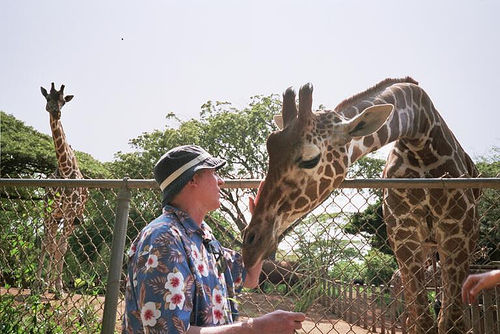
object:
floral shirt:
[123, 202, 249, 334]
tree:
[0, 111, 115, 179]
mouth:
[248, 255, 264, 269]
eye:
[297, 151, 324, 169]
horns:
[50, 82, 55, 92]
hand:
[247, 308, 306, 334]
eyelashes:
[300, 151, 323, 168]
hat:
[152, 143, 227, 209]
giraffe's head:
[239, 82, 394, 269]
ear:
[345, 103, 392, 137]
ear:
[270, 114, 284, 132]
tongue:
[242, 257, 263, 289]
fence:
[0, 170, 499, 333]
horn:
[60, 84, 65, 93]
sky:
[0, 0, 498, 169]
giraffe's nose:
[240, 229, 258, 245]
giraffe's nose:
[54, 109, 62, 116]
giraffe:
[32, 81, 90, 303]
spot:
[428, 131, 451, 164]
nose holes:
[246, 235, 255, 243]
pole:
[100, 188, 132, 333]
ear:
[187, 173, 199, 189]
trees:
[60, 200, 162, 294]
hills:
[0, 110, 232, 297]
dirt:
[291, 297, 381, 333]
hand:
[460, 268, 499, 303]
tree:
[101, 92, 387, 294]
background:
[0, 0, 499, 333]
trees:
[343, 161, 499, 278]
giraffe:
[239, 75, 484, 333]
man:
[122, 144, 305, 334]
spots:
[398, 194, 416, 253]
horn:
[297, 82, 314, 124]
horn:
[280, 86, 299, 129]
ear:
[62, 95, 75, 103]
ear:
[40, 86, 47, 99]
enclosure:
[0, 75, 499, 328]